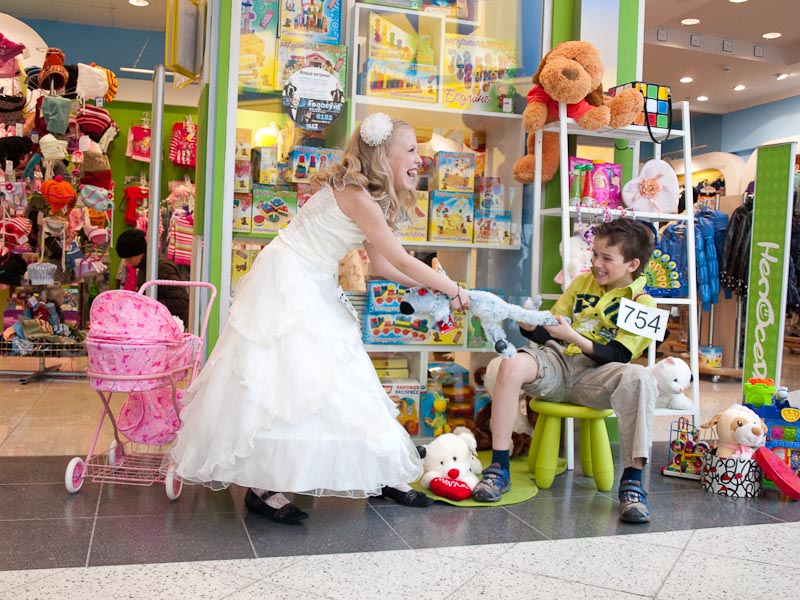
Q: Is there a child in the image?
A: Yes, there is a child.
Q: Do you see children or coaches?
A: Yes, there is a child.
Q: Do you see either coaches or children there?
A: Yes, there is a child.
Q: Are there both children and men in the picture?
A: No, there is a child but no men.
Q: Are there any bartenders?
A: No, there are no bartenders.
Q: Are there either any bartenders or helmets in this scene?
A: No, there are no bartenders or helmets.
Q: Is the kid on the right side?
A: Yes, the kid is on the right of the image.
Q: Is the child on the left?
A: No, the child is on the right of the image.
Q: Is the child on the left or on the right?
A: The child is on the right of the image.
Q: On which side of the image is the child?
A: The child is on the right of the image.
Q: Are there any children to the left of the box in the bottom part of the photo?
A: Yes, there is a child to the left of the box.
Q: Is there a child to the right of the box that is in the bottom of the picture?
A: No, the child is to the left of the box.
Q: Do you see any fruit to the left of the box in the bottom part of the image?
A: No, there is a child to the left of the box.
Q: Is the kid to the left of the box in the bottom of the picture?
A: Yes, the kid is to the left of the box.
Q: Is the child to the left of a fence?
A: No, the child is to the left of the box.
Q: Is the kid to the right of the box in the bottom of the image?
A: No, the kid is to the left of the box.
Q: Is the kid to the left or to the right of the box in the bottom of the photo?
A: The kid is to the left of the box.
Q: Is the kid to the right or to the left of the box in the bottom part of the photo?
A: The kid is to the left of the box.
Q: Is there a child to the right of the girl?
A: Yes, there is a child to the right of the girl.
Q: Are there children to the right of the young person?
A: Yes, there is a child to the right of the girl.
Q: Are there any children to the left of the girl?
A: No, the child is to the right of the girl.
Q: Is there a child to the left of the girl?
A: No, the child is to the right of the girl.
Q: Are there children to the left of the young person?
A: No, the child is to the right of the girl.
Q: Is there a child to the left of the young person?
A: No, the child is to the right of the girl.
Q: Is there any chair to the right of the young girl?
A: No, there is a child to the right of the girl.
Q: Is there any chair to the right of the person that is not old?
A: No, there is a child to the right of the girl.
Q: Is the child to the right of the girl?
A: Yes, the child is to the right of the girl.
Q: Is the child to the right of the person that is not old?
A: Yes, the child is to the right of the girl.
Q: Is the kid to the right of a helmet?
A: No, the kid is to the right of the girl.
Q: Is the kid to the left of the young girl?
A: No, the kid is to the right of the girl.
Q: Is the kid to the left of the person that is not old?
A: No, the kid is to the right of the girl.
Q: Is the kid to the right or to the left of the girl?
A: The kid is to the right of the girl.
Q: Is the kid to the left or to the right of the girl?
A: The kid is to the right of the girl.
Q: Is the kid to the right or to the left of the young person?
A: The kid is to the right of the girl.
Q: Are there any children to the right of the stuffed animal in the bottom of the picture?
A: Yes, there is a child to the right of the stuffed animal.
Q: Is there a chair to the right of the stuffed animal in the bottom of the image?
A: No, there is a child to the right of the stuffed animal.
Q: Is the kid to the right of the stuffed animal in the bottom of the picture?
A: Yes, the kid is to the right of the stuffed animal.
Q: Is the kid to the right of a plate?
A: No, the kid is to the right of the stuffed animal.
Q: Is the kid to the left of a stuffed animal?
A: No, the kid is to the right of a stuffed animal.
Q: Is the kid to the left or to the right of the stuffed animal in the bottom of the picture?
A: The kid is to the right of the stuffed animal.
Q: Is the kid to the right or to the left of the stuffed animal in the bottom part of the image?
A: The kid is to the right of the stuffed animal.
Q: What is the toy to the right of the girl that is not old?
A: The toy is a stuffed animal.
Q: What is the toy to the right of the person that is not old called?
A: The toy is a stuffed animal.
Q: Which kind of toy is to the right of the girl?
A: The toy is a stuffed animal.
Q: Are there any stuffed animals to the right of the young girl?
A: Yes, there is a stuffed animal to the right of the girl.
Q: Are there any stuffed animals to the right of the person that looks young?
A: Yes, there is a stuffed animal to the right of the girl.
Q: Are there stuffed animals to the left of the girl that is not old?
A: No, the stuffed animal is to the right of the girl.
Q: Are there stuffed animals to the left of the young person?
A: No, the stuffed animal is to the right of the girl.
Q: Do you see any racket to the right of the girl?
A: No, there is a stuffed animal to the right of the girl.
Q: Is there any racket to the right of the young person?
A: No, there is a stuffed animal to the right of the girl.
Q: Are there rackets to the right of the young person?
A: No, there is a stuffed animal to the right of the girl.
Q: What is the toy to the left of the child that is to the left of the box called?
A: The toy is a stuffed animal.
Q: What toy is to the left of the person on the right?
A: The toy is a stuffed animal.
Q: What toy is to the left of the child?
A: The toy is a stuffed animal.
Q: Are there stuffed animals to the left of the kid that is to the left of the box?
A: Yes, there is a stuffed animal to the left of the kid.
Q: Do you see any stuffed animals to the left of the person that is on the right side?
A: Yes, there is a stuffed animal to the left of the kid.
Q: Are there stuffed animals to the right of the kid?
A: No, the stuffed animal is to the left of the kid.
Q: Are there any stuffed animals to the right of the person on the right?
A: No, the stuffed animal is to the left of the kid.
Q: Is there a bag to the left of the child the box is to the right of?
A: No, there is a stuffed animal to the left of the child.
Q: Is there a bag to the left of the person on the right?
A: No, there is a stuffed animal to the left of the child.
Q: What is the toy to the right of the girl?
A: The toy is a stuffed animal.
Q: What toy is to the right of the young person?
A: The toy is a stuffed animal.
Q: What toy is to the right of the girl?
A: The toy is a stuffed animal.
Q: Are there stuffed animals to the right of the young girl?
A: Yes, there is a stuffed animal to the right of the girl.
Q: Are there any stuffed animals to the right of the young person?
A: Yes, there is a stuffed animal to the right of the girl.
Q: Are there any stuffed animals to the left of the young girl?
A: No, the stuffed animal is to the right of the girl.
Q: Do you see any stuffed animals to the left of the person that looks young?
A: No, the stuffed animal is to the right of the girl.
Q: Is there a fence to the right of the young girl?
A: No, there is a stuffed animal to the right of the girl.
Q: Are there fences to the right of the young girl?
A: No, there is a stuffed animal to the right of the girl.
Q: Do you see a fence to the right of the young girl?
A: No, there is a stuffed animal to the right of the girl.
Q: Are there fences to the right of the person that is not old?
A: No, there is a stuffed animal to the right of the girl.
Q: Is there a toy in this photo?
A: Yes, there is a toy.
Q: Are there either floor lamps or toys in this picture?
A: Yes, there is a toy.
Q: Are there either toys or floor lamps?
A: Yes, there is a toy.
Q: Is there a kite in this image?
A: No, there are no kites.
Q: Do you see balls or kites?
A: No, there are no kites or balls.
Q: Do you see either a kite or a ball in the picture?
A: No, there are no kites or balls.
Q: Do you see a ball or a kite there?
A: No, there are no kites or balls.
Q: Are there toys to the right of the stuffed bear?
A: Yes, there is a toy to the right of the stuffed bear.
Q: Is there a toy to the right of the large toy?
A: Yes, there is a toy to the right of the stuffed bear.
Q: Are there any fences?
A: No, there are no fences.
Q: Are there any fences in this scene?
A: No, there are no fences.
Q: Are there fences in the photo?
A: No, there are no fences.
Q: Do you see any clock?
A: No, there are no clocks.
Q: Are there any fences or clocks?
A: No, there are no clocks or fences.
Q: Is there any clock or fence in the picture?
A: No, there are no clocks or fences.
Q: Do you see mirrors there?
A: No, there are no mirrors.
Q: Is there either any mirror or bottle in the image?
A: No, there are no mirrors or bottles.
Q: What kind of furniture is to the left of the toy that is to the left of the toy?
A: The piece of furniture is a shelf.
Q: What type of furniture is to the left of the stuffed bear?
A: The piece of furniture is a shelf.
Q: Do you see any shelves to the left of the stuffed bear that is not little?
A: Yes, there is a shelf to the left of the stuffed bear.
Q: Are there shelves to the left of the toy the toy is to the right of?
A: Yes, there is a shelf to the left of the stuffed bear.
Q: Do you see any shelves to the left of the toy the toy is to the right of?
A: Yes, there is a shelf to the left of the stuffed bear.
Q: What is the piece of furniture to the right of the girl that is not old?
A: The piece of furniture is a shelf.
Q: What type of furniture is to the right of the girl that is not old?
A: The piece of furniture is a shelf.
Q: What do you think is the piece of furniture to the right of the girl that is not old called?
A: The piece of furniture is a shelf.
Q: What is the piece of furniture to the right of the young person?
A: The piece of furniture is a shelf.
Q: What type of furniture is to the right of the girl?
A: The piece of furniture is a shelf.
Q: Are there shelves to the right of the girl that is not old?
A: Yes, there is a shelf to the right of the girl.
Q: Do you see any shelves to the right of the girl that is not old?
A: Yes, there is a shelf to the right of the girl.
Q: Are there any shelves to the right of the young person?
A: Yes, there is a shelf to the right of the girl.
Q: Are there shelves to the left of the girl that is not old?
A: No, the shelf is to the right of the girl.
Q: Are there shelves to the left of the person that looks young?
A: No, the shelf is to the right of the girl.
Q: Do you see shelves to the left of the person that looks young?
A: No, the shelf is to the right of the girl.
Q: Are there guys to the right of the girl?
A: No, there is a shelf to the right of the girl.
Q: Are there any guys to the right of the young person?
A: No, there is a shelf to the right of the girl.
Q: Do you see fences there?
A: No, there are no fences.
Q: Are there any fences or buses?
A: No, there are no fences or buses.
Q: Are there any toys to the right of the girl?
A: Yes, there are toys to the right of the girl.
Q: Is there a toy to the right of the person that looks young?
A: Yes, there are toys to the right of the girl.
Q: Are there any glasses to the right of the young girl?
A: No, there are toys to the right of the girl.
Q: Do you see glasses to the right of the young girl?
A: No, there are toys to the right of the girl.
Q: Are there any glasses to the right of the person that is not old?
A: No, there are toys to the right of the girl.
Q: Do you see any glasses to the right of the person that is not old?
A: No, there are toys to the right of the girl.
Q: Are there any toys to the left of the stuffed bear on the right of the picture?
A: Yes, there are toys to the left of the stuffed bear.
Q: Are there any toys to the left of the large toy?
A: Yes, there are toys to the left of the stuffed bear.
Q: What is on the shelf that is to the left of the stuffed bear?
A: The toys are on the shelf.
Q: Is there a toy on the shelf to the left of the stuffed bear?
A: Yes, there are toys on the shelf.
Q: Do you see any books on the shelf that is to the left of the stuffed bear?
A: No, there are toys on the shelf.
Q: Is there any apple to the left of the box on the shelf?
A: No, there are toys to the left of the box.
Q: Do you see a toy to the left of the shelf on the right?
A: Yes, there are toys to the left of the shelf.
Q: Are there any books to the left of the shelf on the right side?
A: No, there are toys to the left of the shelf.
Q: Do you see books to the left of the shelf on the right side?
A: No, there are toys to the left of the shelf.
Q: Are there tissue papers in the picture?
A: No, there are no tissue papers.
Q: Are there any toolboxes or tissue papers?
A: No, there are no tissue papers or toolboxes.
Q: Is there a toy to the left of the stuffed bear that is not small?
A: Yes, there are toys to the left of the stuffed bear.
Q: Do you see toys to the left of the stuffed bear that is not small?
A: Yes, there are toys to the left of the stuffed bear.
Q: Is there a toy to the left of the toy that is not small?
A: Yes, there are toys to the left of the stuffed bear.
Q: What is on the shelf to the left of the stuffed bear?
A: The toys are on the shelf.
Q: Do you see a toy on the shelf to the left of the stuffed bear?
A: Yes, there are toys on the shelf.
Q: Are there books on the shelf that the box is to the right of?
A: No, there are toys on the shelf.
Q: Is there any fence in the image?
A: No, there are no fences.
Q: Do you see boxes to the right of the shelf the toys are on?
A: Yes, there is a box to the right of the shelf.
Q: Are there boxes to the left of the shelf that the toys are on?
A: No, the box is to the right of the shelf.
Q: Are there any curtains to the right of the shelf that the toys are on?
A: No, there is a box to the right of the shelf.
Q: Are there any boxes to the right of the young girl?
A: Yes, there is a box to the right of the girl.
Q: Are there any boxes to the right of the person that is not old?
A: Yes, there is a box to the right of the girl.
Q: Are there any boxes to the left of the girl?
A: No, the box is to the right of the girl.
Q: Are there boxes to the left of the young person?
A: No, the box is to the right of the girl.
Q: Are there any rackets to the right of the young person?
A: No, there is a box to the right of the girl.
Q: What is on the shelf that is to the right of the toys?
A: The box is on the shelf.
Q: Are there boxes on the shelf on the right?
A: Yes, there is a box on the shelf.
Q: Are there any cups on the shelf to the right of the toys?
A: No, there is a box on the shelf.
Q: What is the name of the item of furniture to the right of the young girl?
A: The piece of furniture is a shelf.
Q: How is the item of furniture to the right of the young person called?
A: The piece of furniture is a shelf.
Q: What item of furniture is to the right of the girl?
A: The piece of furniture is a shelf.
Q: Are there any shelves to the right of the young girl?
A: Yes, there is a shelf to the right of the girl.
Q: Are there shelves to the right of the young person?
A: Yes, there is a shelf to the right of the girl.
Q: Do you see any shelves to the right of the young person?
A: Yes, there is a shelf to the right of the girl.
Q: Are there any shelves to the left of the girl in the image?
A: No, the shelf is to the right of the girl.